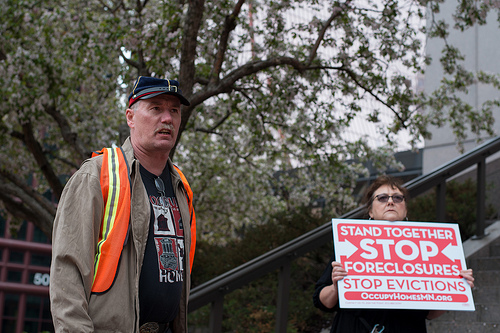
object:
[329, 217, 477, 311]
sign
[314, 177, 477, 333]
woman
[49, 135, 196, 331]
jacket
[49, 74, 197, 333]
man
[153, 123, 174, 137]
mustache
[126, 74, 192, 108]
hat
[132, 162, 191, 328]
shirt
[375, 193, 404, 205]
sunglasses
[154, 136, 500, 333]
railing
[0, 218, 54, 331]
bars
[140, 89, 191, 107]
bill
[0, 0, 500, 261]
tree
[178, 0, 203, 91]
limbs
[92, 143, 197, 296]
vest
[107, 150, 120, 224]
stripe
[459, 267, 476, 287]
hand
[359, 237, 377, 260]
words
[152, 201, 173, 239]
square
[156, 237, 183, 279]
square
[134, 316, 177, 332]
belt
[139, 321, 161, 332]
buckle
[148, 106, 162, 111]
eye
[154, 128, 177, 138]
mouth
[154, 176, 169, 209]
glasses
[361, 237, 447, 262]
stop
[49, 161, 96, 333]
sleeve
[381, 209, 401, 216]
mouth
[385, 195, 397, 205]
nose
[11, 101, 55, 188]
limbs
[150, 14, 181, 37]
leaves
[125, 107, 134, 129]
ear